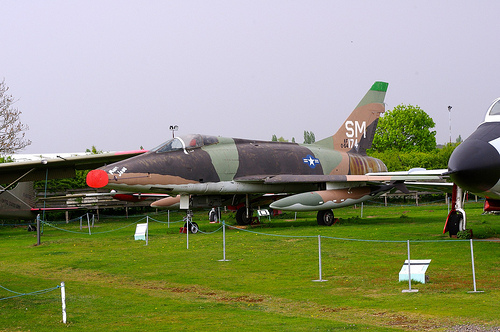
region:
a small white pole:
[60, 282, 70, 323]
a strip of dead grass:
[2, 260, 498, 330]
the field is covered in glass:
[1, 200, 498, 328]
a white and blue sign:
[135, 223, 146, 237]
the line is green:
[35, 218, 471, 245]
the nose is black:
[444, 121, 499, 192]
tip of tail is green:
[370, 82, 389, 90]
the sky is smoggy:
[0, 2, 498, 157]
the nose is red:
[86, 170, 107, 187]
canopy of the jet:
[151, 134, 205, 153]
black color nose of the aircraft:
[443, 147, 488, 190]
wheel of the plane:
[448, 208, 470, 235]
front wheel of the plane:
[185, 222, 198, 232]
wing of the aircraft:
[271, 175, 410, 184]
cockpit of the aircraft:
[161, 134, 213, 153]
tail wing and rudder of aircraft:
[339, 78, 389, 159]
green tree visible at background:
[387, 107, 439, 162]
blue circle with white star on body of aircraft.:
[306, 154, 318, 168]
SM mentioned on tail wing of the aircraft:
[344, 120, 369, 139]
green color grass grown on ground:
[144, 252, 210, 284]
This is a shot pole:
[309, 218, 345, 310]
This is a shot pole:
[399, 230, 436, 308]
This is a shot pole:
[456, 233, 490, 299]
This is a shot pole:
[216, 215, 237, 270]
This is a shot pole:
[184, 208, 207, 269]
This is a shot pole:
[79, 206, 101, 233]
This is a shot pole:
[32, 204, 49, 249]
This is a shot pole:
[51, 275, 74, 329]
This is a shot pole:
[359, 193, 366, 223]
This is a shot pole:
[379, 185, 396, 215]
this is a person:
[380, 96, 497, 213]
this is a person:
[15, 122, 110, 243]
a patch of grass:
[211, 258, 278, 326]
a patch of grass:
[167, 243, 222, 281]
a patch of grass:
[305, 205, 365, 283]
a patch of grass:
[137, 275, 189, 326]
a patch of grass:
[22, 263, 84, 324]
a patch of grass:
[98, 285, 178, 327]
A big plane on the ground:
[442, 86, 486, 211]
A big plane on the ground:
[101, 122, 355, 243]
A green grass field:
[331, 276, 412, 318]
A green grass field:
[130, 294, 265, 329]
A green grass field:
[227, 234, 334, 305]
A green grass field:
[95, 233, 204, 288]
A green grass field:
[362, 212, 447, 244]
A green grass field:
[17, 226, 74, 299]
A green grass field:
[88, 201, 141, 245]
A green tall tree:
[385, 99, 440, 171]